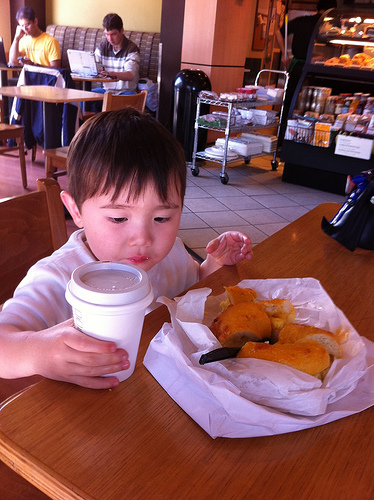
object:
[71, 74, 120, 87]
table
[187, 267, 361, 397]
paper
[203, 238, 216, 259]
thumb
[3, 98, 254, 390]
child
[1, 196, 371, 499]
dining table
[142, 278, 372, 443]
food bag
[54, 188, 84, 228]
right ear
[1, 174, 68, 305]
chair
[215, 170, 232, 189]
cart wheel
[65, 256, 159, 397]
cup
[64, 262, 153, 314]
lid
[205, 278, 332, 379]
bread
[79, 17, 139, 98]
man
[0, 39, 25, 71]
laptop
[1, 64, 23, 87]
table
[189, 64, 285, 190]
cart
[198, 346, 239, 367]
bread knife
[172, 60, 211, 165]
garbage bin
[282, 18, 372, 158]
refrigerated food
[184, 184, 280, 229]
floor tiles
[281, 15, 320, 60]
shirt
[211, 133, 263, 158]
box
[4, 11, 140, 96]
men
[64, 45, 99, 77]
laptops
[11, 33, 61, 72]
shirt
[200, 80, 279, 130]
food